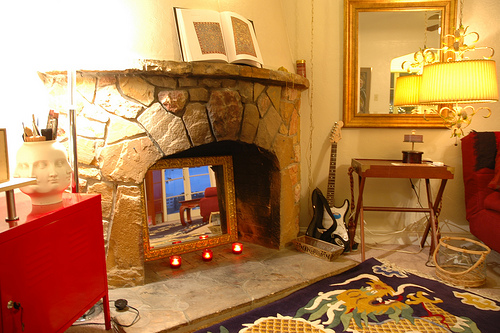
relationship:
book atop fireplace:
[158, 1, 262, 64] [137, 120, 293, 249]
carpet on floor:
[236, 263, 498, 328] [134, 210, 500, 332]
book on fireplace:
[158, 1, 262, 64] [137, 120, 293, 249]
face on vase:
[18, 139, 64, 191] [3, 133, 75, 207]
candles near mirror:
[170, 233, 241, 274] [138, 181, 259, 243]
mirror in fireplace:
[138, 181, 259, 243] [137, 120, 293, 249]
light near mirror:
[405, 27, 499, 156] [349, 4, 438, 118]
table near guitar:
[346, 137, 461, 275] [312, 118, 351, 255]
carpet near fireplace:
[236, 263, 498, 328] [137, 120, 293, 249]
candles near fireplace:
[170, 233, 241, 274] [137, 120, 293, 249]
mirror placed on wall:
[349, 4, 438, 118] [241, 6, 339, 47]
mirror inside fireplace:
[138, 181, 259, 243] [137, 120, 293, 249]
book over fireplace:
[158, 1, 262, 64] [137, 120, 293, 249]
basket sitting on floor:
[442, 236, 487, 303] [134, 210, 500, 332]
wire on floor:
[362, 202, 426, 256] [134, 210, 500, 332]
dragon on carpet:
[306, 270, 431, 332] [236, 263, 498, 328]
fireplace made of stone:
[137, 120, 293, 249] [80, 72, 309, 169]